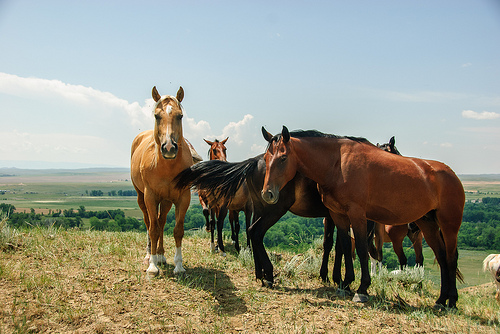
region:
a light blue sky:
[0, 1, 498, 168]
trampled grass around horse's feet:
[1, 226, 496, 332]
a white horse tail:
[480, 246, 497, 276]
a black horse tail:
[169, 148, 263, 200]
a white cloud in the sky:
[460, 105, 497, 118]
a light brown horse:
[130, 83, 196, 283]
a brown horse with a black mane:
[254, 121, 463, 307]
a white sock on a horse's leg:
[172, 242, 187, 273]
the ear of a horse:
[149, 84, 162, 104]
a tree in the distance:
[76, 202, 87, 215]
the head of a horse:
[127, 88, 210, 160]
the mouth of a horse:
[140, 120, 210, 167]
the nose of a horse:
[153, 128, 194, 169]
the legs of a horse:
[126, 193, 217, 293]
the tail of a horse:
[179, 120, 279, 225]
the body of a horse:
[268, 127, 475, 260]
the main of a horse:
[273, 115, 380, 153]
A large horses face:
[155, 92, 181, 154]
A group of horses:
[123, 87, 469, 308]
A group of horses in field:
[111, 81, 491, 313]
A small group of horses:
[51, 70, 485, 319]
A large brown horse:
[255, 122, 475, 312]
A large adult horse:
[253, 117, 483, 314]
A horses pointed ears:
[148, 83, 187, 100]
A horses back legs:
[411, 207, 464, 317]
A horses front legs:
[335, 211, 377, 313]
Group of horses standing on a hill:
[127, 85, 462, 315]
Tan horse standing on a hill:
[128, 85, 190, 280]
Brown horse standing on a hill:
[259, 130, 464, 312]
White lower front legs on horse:
[146, 251, 188, 278]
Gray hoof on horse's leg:
[353, 289, 367, 304]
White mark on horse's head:
[163, 100, 174, 116]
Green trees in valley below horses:
[3, 198, 144, 230]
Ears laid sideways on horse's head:
[205, 135, 235, 159]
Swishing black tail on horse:
[169, 157, 254, 194]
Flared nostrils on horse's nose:
[160, 139, 179, 158]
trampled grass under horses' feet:
[1, 224, 497, 331]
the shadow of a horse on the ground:
[158, 262, 248, 315]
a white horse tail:
[481, 251, 495, 277]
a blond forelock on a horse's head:
[153, 90, 181, 109]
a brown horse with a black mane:
[256, 123, 469, 317]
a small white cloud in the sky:
[462, 110, 498, 120]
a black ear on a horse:
[280, 123, 291, 141]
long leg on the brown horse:
[317, 213, 330, 286]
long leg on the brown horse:
[329, 220, 342, 288]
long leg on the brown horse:
[351, 224, 372, 305]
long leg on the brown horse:
[443, 227, 460, 312]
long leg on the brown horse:
[171, 203, 190, 277]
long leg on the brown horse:
[138, 194, 162, 274]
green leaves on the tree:
[102, 213, 122, 230]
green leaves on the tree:
[125, 223, 136, 233]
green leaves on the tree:
[113, 201, 128, 223]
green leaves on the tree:
[87, 208, 107, 219]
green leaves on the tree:
[43, 218, 74, 226]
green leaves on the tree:
[489, 232, 491, 250]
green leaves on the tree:
[467, 238, 475, 245]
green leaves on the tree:
[289, 228, 292, 250]